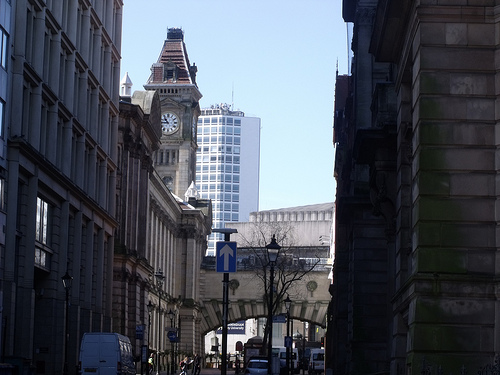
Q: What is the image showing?
A: It is showing a city.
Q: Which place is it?
A: It is a city.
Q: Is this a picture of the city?
A: Yes, it is showing the city.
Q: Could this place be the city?
A: Yes, it is the city.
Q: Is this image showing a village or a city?
A: It is showing a city.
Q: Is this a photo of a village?
A: No, the picture is showing a city.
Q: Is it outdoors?
A: Yes, it is outdoors.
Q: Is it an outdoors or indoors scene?
A: It is outdoors.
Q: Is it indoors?
A: No, it is outdoors.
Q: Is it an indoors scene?
A: No, it is outdoors.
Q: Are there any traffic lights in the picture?
A: No, there are no traffic lights.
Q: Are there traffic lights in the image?
A: No, there are no traffic lights.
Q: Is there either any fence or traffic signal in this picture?
A: No, there are no traffic lights or fences.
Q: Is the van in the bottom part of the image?
A: Yes, the van is in the bottom of the image.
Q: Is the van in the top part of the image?
A: No, the van is in the bottom of the image.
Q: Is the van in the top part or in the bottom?
A: The van is in the bottom of the image.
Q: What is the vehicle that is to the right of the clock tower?
A: The vehicle is a van.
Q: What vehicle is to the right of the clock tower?
A: The vehicle is a van.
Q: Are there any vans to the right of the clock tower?
A: Yes, there is a van to the right of the clock tower.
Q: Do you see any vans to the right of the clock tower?
A: Yes, there is a van to the right of the clock tower.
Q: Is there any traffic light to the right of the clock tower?
A: No, there is a van to the right of the clock tower.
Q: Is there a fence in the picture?
A: No, there are no fences.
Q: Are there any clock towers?
A: Yes, there is a clock tower.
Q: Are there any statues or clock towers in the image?
A: Yes, there is a clock tower.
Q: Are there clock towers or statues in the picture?
A: Yes, there is a clock tower.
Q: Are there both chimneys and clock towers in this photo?
A: No, there is a clock tower but no chimneys.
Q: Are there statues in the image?
A: No, there are no statues.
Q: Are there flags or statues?
A: No, there are no statues or flags.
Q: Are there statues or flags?
A: No, there are no statues or flags.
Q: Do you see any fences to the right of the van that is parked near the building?
A: No, there is a clock tower to the right of the van.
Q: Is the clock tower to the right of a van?
A: Yes, the clock tower is to the right of a van.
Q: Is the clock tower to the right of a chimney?
A: No, the clock tower is to the right of a van.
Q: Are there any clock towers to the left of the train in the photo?
A: Yes, there is a clock tower to the left of the train.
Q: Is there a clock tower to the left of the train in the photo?
A: Yes, there is a clock tower to the left of the train.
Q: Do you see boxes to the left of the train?
A: No, there is a clock tower to the left of the train.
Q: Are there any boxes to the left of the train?
A: No, there is a clock tower to the left of the train.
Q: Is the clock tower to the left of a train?
A: Yes, the clock tower is to the left of a train.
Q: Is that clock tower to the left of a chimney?
A: No, the clock tower is to the left of a train.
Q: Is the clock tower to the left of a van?
A: Yes, the clock tower is to the left of a van.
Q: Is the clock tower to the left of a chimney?
A: No, the clock tower is to the left of a van.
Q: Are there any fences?
A: No, there are no fences.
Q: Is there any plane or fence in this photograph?
A: No, there are no fences or airplanes.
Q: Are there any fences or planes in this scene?
A: No, there are no fences or planes.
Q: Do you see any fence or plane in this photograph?
A: No, there are no fences or airplanes.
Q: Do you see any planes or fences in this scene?
A: No, there are no fences or planes.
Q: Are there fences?
A: No, there are no fences.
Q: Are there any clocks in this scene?
A: Yes, there is a clock.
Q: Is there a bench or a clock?
A: Yes, there is a clock.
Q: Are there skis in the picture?
A: No, there are no skis.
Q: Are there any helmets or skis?
A: No, there are no skis or helmets.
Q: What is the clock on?
A: The clock is on the building.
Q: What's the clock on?
A: The clock is on the building.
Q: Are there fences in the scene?
A: No, there are no fences.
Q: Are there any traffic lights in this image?
A: No, there are no traffic lights.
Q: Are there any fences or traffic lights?
A: No, there are no traffic lights or fences.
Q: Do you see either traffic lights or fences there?
A: No, there are no traffic lights or fences.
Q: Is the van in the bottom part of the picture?
A: Yes, the van is in the bottom of the image.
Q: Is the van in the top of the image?
A: No, the van is in the bottom of the image.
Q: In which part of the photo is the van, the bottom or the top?
A: The van is in the bottom of the image.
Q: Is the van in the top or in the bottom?
A: The van is in the bottom of the image.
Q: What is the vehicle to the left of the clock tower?
A: The vehicle is a van.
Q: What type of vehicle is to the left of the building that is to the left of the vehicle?
A: The vehicle is a van.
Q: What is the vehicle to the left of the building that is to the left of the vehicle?
A: The vehicle is a van.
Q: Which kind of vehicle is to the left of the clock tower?
A: The vehicle is a van.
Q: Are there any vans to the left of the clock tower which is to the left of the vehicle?
A: Yes, there is a van to the left of the clock tower.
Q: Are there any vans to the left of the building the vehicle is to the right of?
A: Yes, there is a van to the left of the clock tower.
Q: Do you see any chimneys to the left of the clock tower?
A: No, there is a van to the left of the clock tower.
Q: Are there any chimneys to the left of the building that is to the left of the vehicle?
A: No, there is a van to the left of the clock tower.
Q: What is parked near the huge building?
A: The van is parked near the building.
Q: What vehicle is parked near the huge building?
A: The vehicle is a van.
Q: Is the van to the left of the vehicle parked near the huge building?
A: Yes, the van is parked near the building.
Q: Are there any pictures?
A: No, there are no pictures.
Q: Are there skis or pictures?
A: No, there are no pictures or skis.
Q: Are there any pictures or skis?
A: No, there are no pictures or skis.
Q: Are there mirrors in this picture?
A: No, there are no mirrors.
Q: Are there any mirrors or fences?
A: No, there are no mirrors or fences.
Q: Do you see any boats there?
A: No, there are no boats.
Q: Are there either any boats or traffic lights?
A: No, there are no boats or traffic lights.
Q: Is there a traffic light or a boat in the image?
A: No, there are no boats or traffic lights.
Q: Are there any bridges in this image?
A: Yes, there is a bridge.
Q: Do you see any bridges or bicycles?
A: Yes, there is a bridge.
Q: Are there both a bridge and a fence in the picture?
A: No, there is a bridge but no fences.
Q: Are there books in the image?
A: No, there are no books.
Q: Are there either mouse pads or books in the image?
A: No, there are no books or mouse pads.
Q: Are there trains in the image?
A: Yes, there is a train.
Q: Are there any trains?
A: Yes, there is a train.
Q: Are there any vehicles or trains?
A: Yes, there is a train.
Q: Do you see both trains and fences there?
A: No, there is a train but no fences.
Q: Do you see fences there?
A: No, there are no fences.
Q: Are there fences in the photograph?
A: No, there are no fences.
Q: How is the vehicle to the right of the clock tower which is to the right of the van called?
A: The vehicle is a train.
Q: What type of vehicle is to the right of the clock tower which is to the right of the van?
A: The vehicle is a train.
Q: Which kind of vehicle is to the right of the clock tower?
A: The vehicle is a train.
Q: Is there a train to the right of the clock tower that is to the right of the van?
A: Yes, there is a train to the right of the clock tower.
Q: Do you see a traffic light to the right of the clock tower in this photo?
A: No, there is a train to the right of the clock tower.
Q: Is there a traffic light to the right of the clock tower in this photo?
A: No, there is a train to the right of the clock tower.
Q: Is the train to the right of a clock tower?
A: Yes, the train is to the right of a clock tower.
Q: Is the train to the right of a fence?
A: No, the train is to the right of a clock tower.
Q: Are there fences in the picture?
A: No, there are no fences.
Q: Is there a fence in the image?
A: No, there are no fences.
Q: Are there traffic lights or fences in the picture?
A: No, there are no fences or traffic lights.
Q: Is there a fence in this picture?
A: No, there are no fences.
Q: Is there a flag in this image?
A: No, there are no flags.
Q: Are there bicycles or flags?
A: No, there are no flags or bicycles.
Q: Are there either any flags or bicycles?
A: No, there are no flags or bicycles.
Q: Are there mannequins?
A: No, there are no mannequins.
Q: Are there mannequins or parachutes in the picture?
A: No, there are no mannequins or parachutes.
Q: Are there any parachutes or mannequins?
A: No, there are no mannequins or parachutes.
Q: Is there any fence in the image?
A: No, there are no fences.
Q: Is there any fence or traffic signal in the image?
A: No, there are no fences or traffic lights.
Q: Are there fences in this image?
A: No, there are no fences.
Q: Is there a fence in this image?
A: No, there are no fences.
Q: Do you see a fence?
A: No, there are no fences.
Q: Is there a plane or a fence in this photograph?
A: No, there are no fences or airplanes.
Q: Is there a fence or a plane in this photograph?
A: No, there are no fences or airplanes.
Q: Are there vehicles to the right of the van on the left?
A: Yes, there is a vehicle to the right of the van.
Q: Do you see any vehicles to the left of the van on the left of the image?
A: No, the vehicle is to the right of the van.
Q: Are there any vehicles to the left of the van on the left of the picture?
A: No, the vehicle is to the right of the van.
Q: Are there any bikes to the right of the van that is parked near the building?
A: No, there is a vehicle to the right of the van.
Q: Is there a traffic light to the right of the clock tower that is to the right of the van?
A: No, there is a vehicle to the right of the clock tower.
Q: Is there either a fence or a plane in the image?
A: No, there are no fences or airplanes.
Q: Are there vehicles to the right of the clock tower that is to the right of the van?
A: Yes, there is a vehicle to the right of the clock tower.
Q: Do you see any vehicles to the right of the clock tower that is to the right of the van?
A: Yes, there is a vehicle to the right of the clock tower.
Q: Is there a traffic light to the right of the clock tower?
A: No, there is a vehicle to the right of the clock tower.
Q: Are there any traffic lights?
A: No, there are no traffic lights.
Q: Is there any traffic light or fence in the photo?
A: No, there are no traffic lights or fences.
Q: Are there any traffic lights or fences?
A: No, there are no traffic lights or fences.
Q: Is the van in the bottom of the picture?
A: Yes, the van is in the bottom of the image.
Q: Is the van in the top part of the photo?
A: No, the van is in the bottom of the image.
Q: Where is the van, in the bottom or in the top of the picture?
A: The van is in the bottom of the image.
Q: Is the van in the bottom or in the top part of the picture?
A: The van is in the bottom of the image.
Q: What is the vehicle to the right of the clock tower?
A: The vehicle is a van.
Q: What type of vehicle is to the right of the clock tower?
A: The vehicle is a van.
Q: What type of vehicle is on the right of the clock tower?
A: The vehicle is a van.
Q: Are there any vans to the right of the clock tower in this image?
A: Yes, there is a van to the right of the clock tower.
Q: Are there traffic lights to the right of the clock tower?
A: No, there is a van to the right of the clock tower.